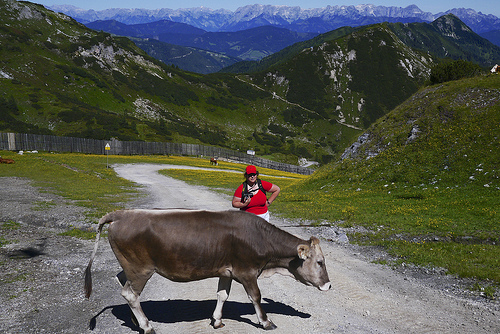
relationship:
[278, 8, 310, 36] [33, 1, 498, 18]
clouds in sky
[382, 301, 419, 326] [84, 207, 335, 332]
pebbles waiting for cow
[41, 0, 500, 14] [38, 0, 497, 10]
clouds in sky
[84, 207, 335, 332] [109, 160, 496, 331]
cow crossing road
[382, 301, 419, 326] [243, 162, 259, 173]
pebbles wearing cap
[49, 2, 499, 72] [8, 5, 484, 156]
mountains in background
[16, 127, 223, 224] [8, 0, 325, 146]
fence on side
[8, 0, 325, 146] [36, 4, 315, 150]
side of mountains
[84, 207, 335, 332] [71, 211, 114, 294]
cow has tail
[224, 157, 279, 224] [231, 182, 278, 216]
person wearing red shirt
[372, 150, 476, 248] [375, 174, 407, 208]
grass has flowers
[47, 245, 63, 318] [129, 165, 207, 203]
rocks on road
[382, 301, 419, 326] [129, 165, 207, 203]
pebbles on road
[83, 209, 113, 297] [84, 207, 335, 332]
tail of cow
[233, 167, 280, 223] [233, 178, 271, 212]
woman wearing red shirt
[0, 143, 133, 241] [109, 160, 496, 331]
area beside road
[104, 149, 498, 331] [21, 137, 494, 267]
path between grass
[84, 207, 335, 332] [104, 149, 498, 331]
cow crossing path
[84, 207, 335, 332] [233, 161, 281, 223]
cow near a woman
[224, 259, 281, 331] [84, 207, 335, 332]
cow leg of cow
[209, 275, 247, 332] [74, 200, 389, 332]
leg of cow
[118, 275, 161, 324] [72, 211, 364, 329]
leg of cow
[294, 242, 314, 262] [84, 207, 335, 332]
ear of cow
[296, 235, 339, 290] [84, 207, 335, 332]
face of cow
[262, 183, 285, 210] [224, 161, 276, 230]
arm on hip of woman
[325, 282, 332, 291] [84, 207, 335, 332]
nose on cow